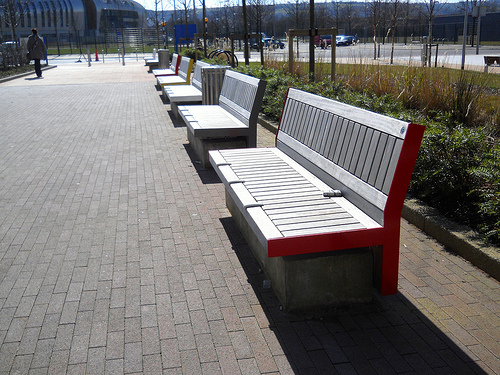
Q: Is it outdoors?
A: Yes, it is outdoors.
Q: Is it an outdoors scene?
A: Yes, it is outdoors.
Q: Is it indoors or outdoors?
A: It is outdoors.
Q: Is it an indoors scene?
A: No, it is outdoors.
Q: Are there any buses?
A: No, there are no buses.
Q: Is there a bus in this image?
A: No, there are no buses.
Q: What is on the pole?
A: The sign is on the pole.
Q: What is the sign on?
A: The sign is on the pole.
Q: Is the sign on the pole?
A: Yes, the sign is on the pole.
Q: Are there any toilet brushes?
A: No, there are no toilet brushes.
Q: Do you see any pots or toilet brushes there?
A: No, there are no toilet brushes or pots.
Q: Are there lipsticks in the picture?
A: No, there are no lipsticks.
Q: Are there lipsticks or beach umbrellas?
A: No, there are no lipsticks or beach umbrellas.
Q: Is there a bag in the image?
A: No, there are no bags.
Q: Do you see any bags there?
A: No, there are no bags.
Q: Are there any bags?
A: No, there are no bags.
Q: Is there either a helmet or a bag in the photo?
A: No, there are no bags or helmets.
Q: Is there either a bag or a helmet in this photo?
A: No, there are no bags or helmets.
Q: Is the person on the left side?
A: Yes, the person is on the left of the image.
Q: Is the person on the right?
A: No, the person is on the left of the image.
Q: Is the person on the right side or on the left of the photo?
A: The person is on the left of the image.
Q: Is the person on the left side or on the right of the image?
A: The person is on the left of the image.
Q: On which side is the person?
A: The person is on the left of the image.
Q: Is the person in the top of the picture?
A: Yes, the person is in the top of the image.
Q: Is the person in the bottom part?
A: No, the person is in the top of the image.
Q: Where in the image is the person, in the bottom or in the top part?
A: The person is in the top of the image.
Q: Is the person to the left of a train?
A: No, the person is to the left of a bench.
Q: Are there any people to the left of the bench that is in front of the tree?
A: Yes, there is a person to the left of the bench.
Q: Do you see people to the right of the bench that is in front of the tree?
A: No, the person is to the left of the bench.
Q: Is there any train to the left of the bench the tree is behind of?
A: No, there is a person to the left of the bench.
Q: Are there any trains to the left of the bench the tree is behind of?
A: No, there is a person to the left of the bench.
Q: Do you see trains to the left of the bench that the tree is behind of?
A: No, there is a person to the left of the bench.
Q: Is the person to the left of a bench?
A: Yes, the person is to the left of a bench.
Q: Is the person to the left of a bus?
A: No, the person is to the left of a bench.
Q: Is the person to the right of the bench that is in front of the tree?
A: No, the person is to the left of the bench.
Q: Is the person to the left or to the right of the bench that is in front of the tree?
A: The person is to the left of the bench.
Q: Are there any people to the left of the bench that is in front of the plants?
A: Yes, there is a person to the left of the bench.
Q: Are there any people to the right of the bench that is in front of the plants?
A: No, the person is to the left of the bench.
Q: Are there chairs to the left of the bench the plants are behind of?
A: No, there is a person to the left of the bench.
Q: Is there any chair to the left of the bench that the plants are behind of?
A: No, there is a person to the left of the bench.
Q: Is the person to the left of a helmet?
A: No, the person is to the left of a bench.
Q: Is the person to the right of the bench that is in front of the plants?
A: No, the person is to the left of the bench.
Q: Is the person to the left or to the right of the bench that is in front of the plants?
A: The person is to the left of the bench.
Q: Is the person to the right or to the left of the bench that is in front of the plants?
A: The person is to the left of the bench.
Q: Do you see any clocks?
A: No, there are no clocks.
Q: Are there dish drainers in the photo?
A: No, there are no dish drainers.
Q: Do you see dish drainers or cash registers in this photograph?
A: No, there are no dish drainers or cash registers.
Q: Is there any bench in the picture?
A: Yes, there is a bench.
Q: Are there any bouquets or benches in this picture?
A: Yes, there is a bench.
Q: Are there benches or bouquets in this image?
A: Yes, there is a bench.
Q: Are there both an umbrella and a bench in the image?
A: No, there is a bench but no umbrellas.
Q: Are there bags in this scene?
A: No, there are no bags.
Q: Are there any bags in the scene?
A: No, there are no bags.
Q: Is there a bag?
A: No, there are no bags.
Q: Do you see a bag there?
A: No, there are no bags.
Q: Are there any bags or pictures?
A: No, there are no bags or pictures.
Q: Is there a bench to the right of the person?
A: Yes, there is a bench to the right of the person.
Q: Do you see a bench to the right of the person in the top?
A: Yes, there is a bench to the right of the person.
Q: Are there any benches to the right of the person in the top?
A: Yes, there is a bench to the right of the person.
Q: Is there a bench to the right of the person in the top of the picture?
A: Yes, there is a bench to the right of the person.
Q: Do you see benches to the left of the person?
A: No, the bench is to the right of the person.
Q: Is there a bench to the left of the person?
A: No, the bench is to the right of the person.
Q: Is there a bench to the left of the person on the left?
A: No, the bench is to the right of the person.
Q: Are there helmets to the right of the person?
A: No, there is a bench to the right of the person.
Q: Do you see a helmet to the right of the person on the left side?
A: No, there is a bench to the right of the person.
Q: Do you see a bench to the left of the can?
A: Yes, there is a bench to the left of the can.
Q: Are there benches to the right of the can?
A: No, the bench is to the left of the can.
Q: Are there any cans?
A: Yes, there is a can.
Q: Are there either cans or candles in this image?
A: Yes, there is a can.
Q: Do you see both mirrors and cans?
A: No, there is a can but no mirrors.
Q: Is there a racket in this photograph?
A: No, there are no rackets.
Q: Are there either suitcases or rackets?
A: No, there are no rackets or suitcases.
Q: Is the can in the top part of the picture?
A: Yes, the can is in the top of the image.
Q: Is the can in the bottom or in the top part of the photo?
A: The can is in the top of the image.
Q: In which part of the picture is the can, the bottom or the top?
A: The can is in the top of the image.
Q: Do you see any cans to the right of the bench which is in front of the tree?
A: Yes, there is a can to the right of the bench.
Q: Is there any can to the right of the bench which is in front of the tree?
A: Yes, there is a can to the right of the bench.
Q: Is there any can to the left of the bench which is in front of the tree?
A: No, the can is to the right of the bench.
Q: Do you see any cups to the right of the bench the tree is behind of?
A: No, there is a can to the right of the bench.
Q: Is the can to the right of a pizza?
A: No, the can is to the right of the bench.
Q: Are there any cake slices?
A: No, there are no cake slices.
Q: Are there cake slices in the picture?
A: No, there are no cake slices.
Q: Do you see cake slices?
A: No, there are no cake slices.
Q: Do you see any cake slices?
A: No, there are no cake slices.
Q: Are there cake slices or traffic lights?
A: No, there are no cake slices or traffic lights.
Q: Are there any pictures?
A: No, there are no pictures.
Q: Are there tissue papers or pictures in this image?
A: No, there are no pictures or tissue papers.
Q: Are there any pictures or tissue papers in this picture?
A: No, there are no pictures or tissue papers.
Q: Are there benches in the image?
A: Yes, there is a bench.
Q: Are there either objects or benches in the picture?
A: Yes, there is a bench.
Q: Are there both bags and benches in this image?
A: No, there is a bench but no bags.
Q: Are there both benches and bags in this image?
A: No, there is a bench but no bags.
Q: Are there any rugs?
A: No, there are no rugs.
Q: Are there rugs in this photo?
A: No, there are no rugs.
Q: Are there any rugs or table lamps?
A: No, there are no rugs or table lamps.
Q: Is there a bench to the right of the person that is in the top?
A: Yes, there is a bench to the right of the person.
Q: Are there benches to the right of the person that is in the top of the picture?
A: Yes, there is a bench to the right of the person.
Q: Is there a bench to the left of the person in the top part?
A: No, the bench is to the right of the person.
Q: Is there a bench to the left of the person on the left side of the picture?
A: No, the bench is to the right of the person.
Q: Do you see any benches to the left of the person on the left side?
A: No, the bench is to the right of the person.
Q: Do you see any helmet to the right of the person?
A: No, there is a bench to the right of the person.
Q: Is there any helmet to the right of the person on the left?
A: No, there is a bench to the right of the person.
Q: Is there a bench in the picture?
A: Yes, there is a bench.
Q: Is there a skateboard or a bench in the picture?
A: Yes, there is a bench.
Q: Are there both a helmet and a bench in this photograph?
A: No, there is a bench but no helmets.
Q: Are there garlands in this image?
A: No, there are no garlands.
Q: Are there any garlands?
A: No, there are no garlands.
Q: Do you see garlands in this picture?
A: No, there are no garlands.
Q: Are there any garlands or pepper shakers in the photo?
A: No, there are no garlands or pepper shakers.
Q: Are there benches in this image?
A: Yes, there is a bench.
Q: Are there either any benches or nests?
A: Yes, there is a bench.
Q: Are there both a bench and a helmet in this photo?
A: No, there is a bench but no helmets.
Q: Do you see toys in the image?
A: No, there are no toys.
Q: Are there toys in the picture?
A: No, there are no toys.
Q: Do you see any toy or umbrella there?
A: No, there are no toys or umbrellas.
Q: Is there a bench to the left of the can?
A: Yes, there is a bench to the left of the can.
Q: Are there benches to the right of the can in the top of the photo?
A: No, the bench is to the left of the can.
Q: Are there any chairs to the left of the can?
A: No, there is a bench to the left of the can.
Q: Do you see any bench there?
A: Yes, there is a bench.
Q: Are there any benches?
A: Yes, there is a bench.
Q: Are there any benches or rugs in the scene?
A: Yes, there is a bench.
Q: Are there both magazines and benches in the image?
A: No, there is a bench but no magazines.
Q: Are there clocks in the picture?
A: No, there are no clocks.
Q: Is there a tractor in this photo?
A: No, there are no tractors.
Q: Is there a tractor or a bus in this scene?
A: No, there are no tractors or buses.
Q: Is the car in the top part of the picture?
A: Yes, the car is in the top of the image.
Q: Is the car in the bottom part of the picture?
A: No, the car is in the top of the image.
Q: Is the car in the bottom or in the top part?
A: The car is in the top of the image.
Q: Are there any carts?
A: No, there are no carts.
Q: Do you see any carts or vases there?
A: No, there are no carts or vases.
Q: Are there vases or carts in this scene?
A: No, there are no carts or vases.